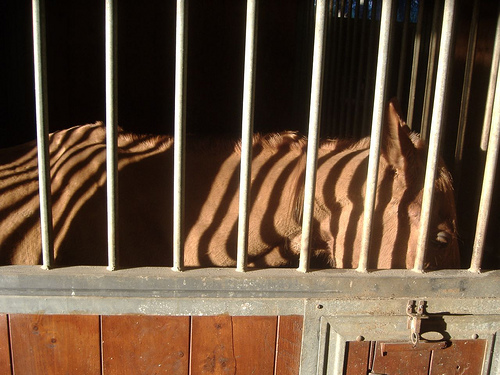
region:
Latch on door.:
[393, 299, 442, 351]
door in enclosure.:
[320, 310, 498, 374]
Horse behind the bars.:
[2, 103, 482, 271]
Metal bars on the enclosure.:
[0, 1, 490, 271]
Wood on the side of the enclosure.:
[1, 313, 301, 372]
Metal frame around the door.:
[297, 294, 498, 374]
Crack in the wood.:
[217, 316, 240, 373]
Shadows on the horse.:
[0, 98, 457, 273]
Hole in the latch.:
[409, 328, 418, 341]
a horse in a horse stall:
[5, 5, 483, 340]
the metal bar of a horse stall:
[28, 0, 54, 268]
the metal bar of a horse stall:
[93, 0, 131, 271]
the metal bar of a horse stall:
[168, 0, 189, 270]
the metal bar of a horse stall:
[233, 1, 263, 276]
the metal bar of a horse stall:
[291, 0, 328, 279]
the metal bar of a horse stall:
[348, 0, 395, 268]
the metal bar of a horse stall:
[415, 0, 460, 275]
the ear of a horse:
[382, 98, 418, 188]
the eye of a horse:
[421, 227, 453, 250]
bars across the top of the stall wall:
[13, 32, 423, 266]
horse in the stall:
[56, 79, 496, 261]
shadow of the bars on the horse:
[216, 146, 433, 270]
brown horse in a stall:
[37, 155, 474, 276]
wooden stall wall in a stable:
[6, 334, 298, 372]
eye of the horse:
[429, 223, 458, 265]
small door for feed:
[323, 310, 496, 374]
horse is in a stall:
[11, 86, 368, 316]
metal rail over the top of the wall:
[18, 270, 246, 295]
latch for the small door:
[403, 301, 424, 350]